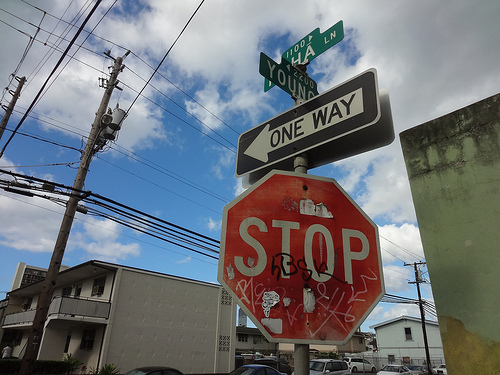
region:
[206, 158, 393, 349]
grafitti covering stop sign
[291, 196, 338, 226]
tore sticker on stop sign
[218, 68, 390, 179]
one way sign above stop sign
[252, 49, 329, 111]
street sign above one way sign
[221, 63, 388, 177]
one way sign pointing left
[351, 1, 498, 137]
gray cloud above building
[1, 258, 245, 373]
set of apartment buildings behind power pole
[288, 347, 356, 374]
white van parked on side of road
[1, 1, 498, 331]
sky is partly cloudy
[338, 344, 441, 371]
fence in front of building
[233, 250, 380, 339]
gang signs and graffiti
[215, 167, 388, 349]
stop sign on the corner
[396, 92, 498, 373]
unknown cement building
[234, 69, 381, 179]
one way sign pointed left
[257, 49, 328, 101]
green sign that says 2200 young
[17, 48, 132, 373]
pole that is used for electric and phone lines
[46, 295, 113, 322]
balcony with a completely closed in fencing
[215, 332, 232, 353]
thick, square, bubble windows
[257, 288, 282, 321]
sticker that made it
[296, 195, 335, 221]
sticker that didn't make it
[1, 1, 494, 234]
a sky with some clouds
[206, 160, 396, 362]
a stop sign with graffiti on it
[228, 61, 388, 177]
a black and white ONE WAY sign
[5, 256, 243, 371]
a white building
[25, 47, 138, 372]
a tan phone line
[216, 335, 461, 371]
a parking lot of cars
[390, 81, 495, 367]
a building on the right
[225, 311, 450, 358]
some building behind a group of cars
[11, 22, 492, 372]
a scene happening during the day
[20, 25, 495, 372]
a scene outside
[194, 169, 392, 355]
red and white stop sign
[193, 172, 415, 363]
stop sign with graffiti on it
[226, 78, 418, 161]
black and white sign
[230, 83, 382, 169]
white arrow with black writing in it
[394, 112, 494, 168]
top of the building is black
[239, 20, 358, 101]
green and white street signs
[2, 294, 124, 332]
balcony on the second floor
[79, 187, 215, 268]
several black wires running along the poles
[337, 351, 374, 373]
white van that is parked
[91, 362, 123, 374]
top of a small bush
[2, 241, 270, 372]
Two story apartment building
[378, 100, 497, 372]
Large concrete stucture with no windows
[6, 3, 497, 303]
Blue sky with clouds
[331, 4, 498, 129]
Dark heavy cloud on right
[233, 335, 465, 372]
Parking lot full of cars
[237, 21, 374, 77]
Green street sign with 1100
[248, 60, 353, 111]
Green street sign that says young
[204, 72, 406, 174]
One way street sign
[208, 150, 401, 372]
Red and white STOP sign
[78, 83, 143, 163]
Three power transformers on the telephone/power poles